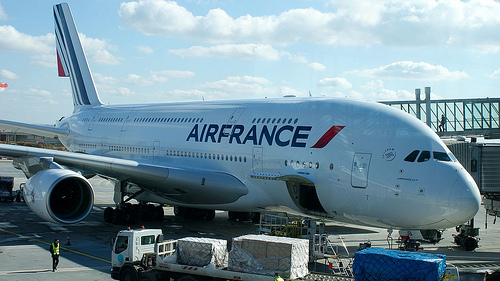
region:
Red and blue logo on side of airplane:
[188, 123, 348, 145]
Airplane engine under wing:
[22, 165, 96, 223]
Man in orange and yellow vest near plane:
[47, 239, 62, 271]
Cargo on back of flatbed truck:
[178, 233, 309, 278]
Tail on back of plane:
[51, 0, 102, 107]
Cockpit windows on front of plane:
[405, 147, 452, 164]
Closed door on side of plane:
[348, 151, 371, 189]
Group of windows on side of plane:
[164, 150, 247, 163]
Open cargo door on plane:
[250, 164, 332, 218]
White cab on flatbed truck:
[111, 225, 164, 276]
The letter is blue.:
[184, 123, 200, 143]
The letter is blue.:
[196, 117, 208, 143]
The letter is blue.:
[203, 117, 218, 147]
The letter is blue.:
[217, 115, 233, 145]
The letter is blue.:
[227, 115, 244, 147]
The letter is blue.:
[241, 120, 257, 146]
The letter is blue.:
[254, 117, 276, 154]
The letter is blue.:
[274, 118, 294, 149]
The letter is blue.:
[287, 117, 315, 157]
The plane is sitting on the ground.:
[5, 0, 488, 279]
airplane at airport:
[30, 33, 446, 229]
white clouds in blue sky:
[146, 17, 192, 88]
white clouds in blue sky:
[253, 29, 336, 71]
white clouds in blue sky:
[14, 33, 31, 66]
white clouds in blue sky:
[141, 40, 191, 77]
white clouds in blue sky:
[382, 33, 458, 70]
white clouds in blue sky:
[287, 53, 331, 79]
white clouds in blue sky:
[203, 31, 247, 59]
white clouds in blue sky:
[257, 8, 298, 68]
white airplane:
[34, 30, 443, 234]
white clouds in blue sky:
[94, 17, 125, 37]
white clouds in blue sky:
[16, 25, 31, 48]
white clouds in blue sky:
[13, 60, 35, 96]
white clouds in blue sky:
[112, 13, 137, 48]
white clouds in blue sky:
[155, 15, 187, 46]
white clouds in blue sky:
[181, 8, 221, 54]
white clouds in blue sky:
[288, 21, 332, 46]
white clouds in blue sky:
[366, 22, 424, 56]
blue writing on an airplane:
[176, 123, 313, 148]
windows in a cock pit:
[406, 147, 457, 169]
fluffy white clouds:
[187, 12, 280, 59]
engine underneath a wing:
[23, 160, 96, 226]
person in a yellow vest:
[45, 233, 68, 273]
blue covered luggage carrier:
[352, 240, 442, 278]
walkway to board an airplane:
[435, 125, 495, 200]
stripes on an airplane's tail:
[45, 5, 95, 120]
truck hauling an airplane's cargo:
[100, 217, 310, 277]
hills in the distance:
[3, 110, 68, 152]